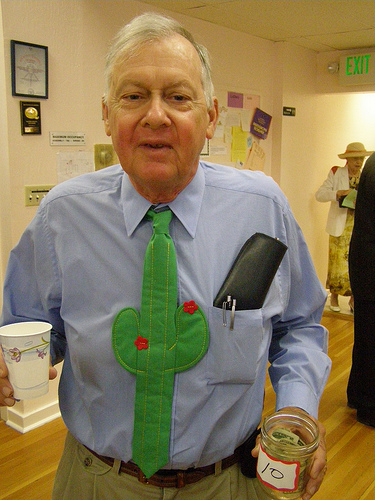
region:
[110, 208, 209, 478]
a man with a novelty cactus tie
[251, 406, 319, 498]
an empty jar full of money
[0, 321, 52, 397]
a man holding a white cup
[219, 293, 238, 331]
a man with two pens in his pocket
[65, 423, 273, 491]
a man wearing a brown belt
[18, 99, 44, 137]
a plaque on a wall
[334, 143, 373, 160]
a woman wearing a yellow hat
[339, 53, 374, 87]
an exit sign on a wall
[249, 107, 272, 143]
a pamphlet on a wall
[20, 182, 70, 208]
a light switch on a wall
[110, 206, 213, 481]
green, red, and yellow cactus tie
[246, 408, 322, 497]
glass jar in man's hand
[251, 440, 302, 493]
red and white sticker on glass jar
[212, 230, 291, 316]
black eyeglass case in shirt pocket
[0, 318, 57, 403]
white paper cup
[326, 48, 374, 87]
exit sign above doorway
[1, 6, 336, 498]
man in blue shirt standing in room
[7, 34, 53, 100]
framed object hanging on wall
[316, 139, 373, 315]
woman in white jacket standing in doorway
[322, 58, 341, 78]
light attatched to exit sign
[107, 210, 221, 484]
a green felt tie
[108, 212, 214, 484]
this is a novelty tie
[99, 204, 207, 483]
his tie is shaped like a cactus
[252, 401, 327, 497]
there is money in the jar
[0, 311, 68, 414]
this is a paper cup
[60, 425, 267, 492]
this is a brown leather belt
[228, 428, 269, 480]
a holster for a cell phone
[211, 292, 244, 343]
pens in his pocket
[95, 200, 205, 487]
The tie is shaped like a cactus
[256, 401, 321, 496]
A small glass jar in the man's hand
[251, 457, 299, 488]
The white paper says 10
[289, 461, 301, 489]
The red outline of the small white tag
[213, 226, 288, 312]
A black pocketbook in the man's pocket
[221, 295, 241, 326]
Pens hanging on the man's pocket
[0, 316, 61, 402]
A paper cup in the man's hand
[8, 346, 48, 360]
A small purple flower on the paper cup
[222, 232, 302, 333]
glass case sitting in shirt pocket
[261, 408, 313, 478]
money sitting in side jar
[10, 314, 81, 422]
man holding a cup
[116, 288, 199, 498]
man wearing a catus tie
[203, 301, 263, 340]
pen sitting in shirt pocket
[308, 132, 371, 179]
woman wearing a hat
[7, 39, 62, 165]
plaques hanging on a wall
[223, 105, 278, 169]
paper hanging on a wall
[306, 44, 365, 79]
exit sign hanging above a doorway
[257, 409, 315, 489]
Money in the jar.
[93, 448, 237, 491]
The belt is brown.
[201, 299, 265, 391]
Pocket on the shirt.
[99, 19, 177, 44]
The hair is grey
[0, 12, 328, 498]
a senior man wearing a funny necktie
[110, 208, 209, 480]
the man's necktie shaped like a cactus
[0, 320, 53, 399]
a paper cup in the man's hand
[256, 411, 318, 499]
a jar with money in the man's hand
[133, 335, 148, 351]
a red flower on the cactus necktie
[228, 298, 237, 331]
a pen in the man's shirt pocket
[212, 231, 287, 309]
black eyeglasses case in the man's shirt pocket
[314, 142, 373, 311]
a woman wearing a hat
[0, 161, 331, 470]
the blue shirt the man is wearing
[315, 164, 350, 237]
the white jacket on the lady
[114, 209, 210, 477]
green cactus style neck tie